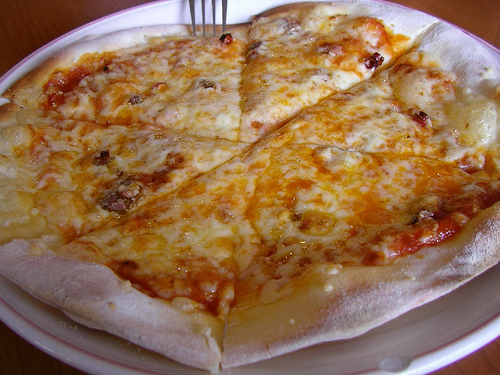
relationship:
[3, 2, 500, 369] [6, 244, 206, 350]
pizza has crust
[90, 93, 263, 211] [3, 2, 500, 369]
cheese on pizza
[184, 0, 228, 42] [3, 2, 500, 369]
fork on pizza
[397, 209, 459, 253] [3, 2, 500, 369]
sauce on pizza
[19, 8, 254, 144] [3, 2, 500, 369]
slice of pizza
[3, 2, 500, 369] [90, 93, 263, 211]
pizza has cheese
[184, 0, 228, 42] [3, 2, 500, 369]
fork for pizza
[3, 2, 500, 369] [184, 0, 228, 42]
pizza has fork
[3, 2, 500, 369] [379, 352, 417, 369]
plate has chip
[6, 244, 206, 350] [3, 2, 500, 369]
crust on pizza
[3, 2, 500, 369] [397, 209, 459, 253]
pizza has sauce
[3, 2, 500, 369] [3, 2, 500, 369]
pizza on plate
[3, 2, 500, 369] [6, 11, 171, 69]
plate has border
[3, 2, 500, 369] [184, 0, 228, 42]
plate has fork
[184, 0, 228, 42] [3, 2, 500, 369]
fork on plate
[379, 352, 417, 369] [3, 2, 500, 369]
chip on plate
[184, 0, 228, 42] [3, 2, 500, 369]
fork in pizza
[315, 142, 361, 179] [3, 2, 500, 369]
bubble on pizza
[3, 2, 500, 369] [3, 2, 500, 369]
plate holding pizza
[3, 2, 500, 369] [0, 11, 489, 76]
plate on table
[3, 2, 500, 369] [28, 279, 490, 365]
pizza cast shadow